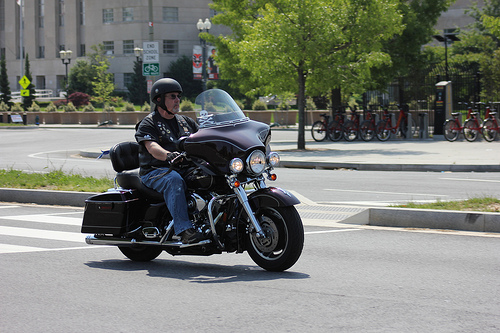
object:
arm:
[133, 122, 173, 162]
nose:
[174, 99, 181, 107]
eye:
[168, 95, 176, 98]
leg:
[136, 170, 213, 234]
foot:
[183, 228, 205, 243]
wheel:
[238, 191, 305, 274]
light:
[247, 150, 265, 174]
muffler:
[83, 234, 139, 246]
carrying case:
[80, 190, 144, 234]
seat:
[116, 167, 162, 200]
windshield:
[192, 88, 249, 128]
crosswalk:
[3, 174, 498, 254]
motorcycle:
[78, 87, 306, 272]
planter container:
[57, 110, 83, 121]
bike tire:
[309, 120, 326, 142]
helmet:
[149, 76, 182, 98]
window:
[97, 7, 115, 23]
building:
[4, 3, 237, 93]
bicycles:
[375, 102, 410, 142]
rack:
[313, 103, 499, 143]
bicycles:
[440, 113, 463, 143]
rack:
[440, 106, 499, 142]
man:
[134, 77, 214, 249]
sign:
[18, 74, 30, 99]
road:
[1, 126, 495, 328]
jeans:
[139, 165, 195, 236]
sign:
[139, 40, 160, 63]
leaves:
[339, 3, 378, 83]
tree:
[220, 0, 354, 151]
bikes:
[357, 108, 375, 142]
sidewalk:
[322, 138, 479, 148]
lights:
[204, 19, 212, 30]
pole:
[201, 40, 212, 84]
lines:
[12, 243, 45, 253]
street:
[35, 267, 137, 314]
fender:
[269, 185, 302, 208]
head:
[145, 77, 183, 115]